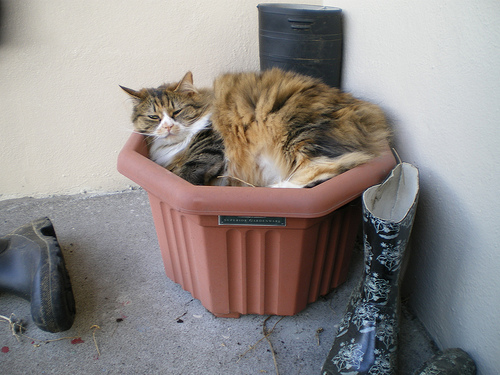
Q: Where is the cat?
A: In the bucket.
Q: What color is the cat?
A: Brown, white, and black.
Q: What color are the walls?
A: White.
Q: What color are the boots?
A: Black and white.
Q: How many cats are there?
A: One.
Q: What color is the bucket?
A: Red.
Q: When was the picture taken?
A: Daytime.